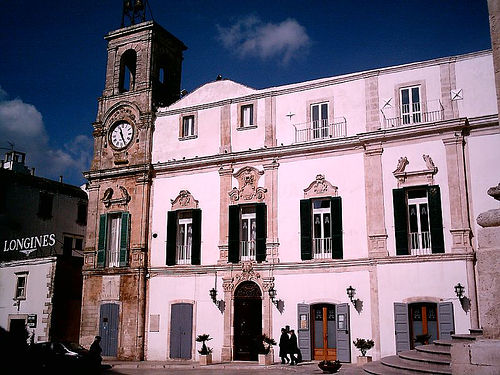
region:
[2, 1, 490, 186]
clouds in blue sky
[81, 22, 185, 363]
clock on face of tower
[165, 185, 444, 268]
windows with black shutters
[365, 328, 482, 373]
set of round steps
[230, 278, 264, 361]
door with arched top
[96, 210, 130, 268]
green shutters on window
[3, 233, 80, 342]
word on roof of building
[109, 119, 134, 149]
clock with white face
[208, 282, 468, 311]
lights on surface of wall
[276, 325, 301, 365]
people walking next to building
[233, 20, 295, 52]
cloud in the sky.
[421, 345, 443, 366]
steps near the building.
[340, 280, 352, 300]
light on the building.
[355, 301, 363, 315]
shadow on the building.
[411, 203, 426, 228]
windows on the building.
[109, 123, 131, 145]
clock on the tower.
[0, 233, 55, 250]
writing on the building.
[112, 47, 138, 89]
arched window above clock.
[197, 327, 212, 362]
plant near the sidewalk.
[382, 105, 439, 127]
balcony on third floor.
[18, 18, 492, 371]
picture of buildings in a town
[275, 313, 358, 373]
two people walking in front of building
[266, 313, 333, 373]
two people wearing black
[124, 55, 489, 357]
two toned pink building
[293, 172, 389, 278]
window with black shutters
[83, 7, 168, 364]
a clock on a tower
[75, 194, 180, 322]
window with green shutters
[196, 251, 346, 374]
a door leading into the building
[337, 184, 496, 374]
a cement stairway leading up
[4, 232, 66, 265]
a "Longines" sign over a building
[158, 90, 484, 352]
a large pink building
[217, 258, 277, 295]
scrollwork over a doorway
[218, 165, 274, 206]
scrollwork over a window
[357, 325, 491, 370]
a large staircase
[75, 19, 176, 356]
a large brick tower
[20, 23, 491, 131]
a mostly clear sky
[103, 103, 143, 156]
a large clock on a tower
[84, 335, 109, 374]
a man by a car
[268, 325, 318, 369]
people walking by a building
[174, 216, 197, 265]
window on an old white building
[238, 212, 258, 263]
window on an old white building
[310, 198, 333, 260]
window on an old white building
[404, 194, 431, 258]
window on an old white building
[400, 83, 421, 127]
window on an old white building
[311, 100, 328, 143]
window on an old white building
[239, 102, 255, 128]
window on an old white building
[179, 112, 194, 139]
window on an old white building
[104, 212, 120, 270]
window on an old white building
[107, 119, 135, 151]
white clock on an old building